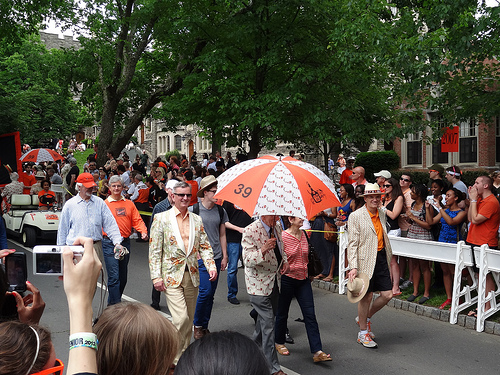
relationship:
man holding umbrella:
[241, 215, 290, 373] [212, 155, 344, 239]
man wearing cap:
[56, 171, 130, 264] [75, 171, 98, 188]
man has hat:
[348, 182, 395, 349] [359, 181, 386, 197]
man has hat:
[348, 182, 395, 349] [346, 273, 371, 304]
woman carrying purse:
[276, 216, 334, 364] [302, 228, 324, 277]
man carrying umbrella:
[241, 215, 290, 373] [212, 155, 344, 239]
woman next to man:
[276, 216, 334, 364] [241, 215, 290, 373]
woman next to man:
[276, 216, 334, 364] [348, 182, 395, 349]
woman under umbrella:
[276, 216, 334, 364] [212, 155, 344, 239]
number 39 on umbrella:
[234, 183, 253, 199] [212, 155, 344, 239]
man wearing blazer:
[241, 215, 290, 373] [241, 218, 289, 297]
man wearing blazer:
[348, 182, 395, 349] [346, 204, 394, 282]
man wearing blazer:
[149, 181, 221, 366] [149, 206, 218, 289]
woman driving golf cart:
[37, 179, 57, 212] [2, 193, 63, 247]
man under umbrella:
[241, 215, 290, 373] [212, 155, 344, 239]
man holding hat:
[348, 182, 395, 349] [346, 273, 371, 304]